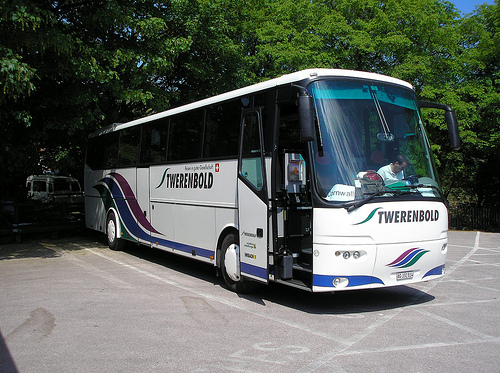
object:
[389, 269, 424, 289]
license plate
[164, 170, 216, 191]
writing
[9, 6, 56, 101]
leaves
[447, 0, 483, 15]
sky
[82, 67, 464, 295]
bus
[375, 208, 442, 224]
word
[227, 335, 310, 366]
es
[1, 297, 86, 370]
ground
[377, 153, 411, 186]
man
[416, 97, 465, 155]
mirror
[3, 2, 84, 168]
trees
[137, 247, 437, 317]
shadow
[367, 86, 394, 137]
wipers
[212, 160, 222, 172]
square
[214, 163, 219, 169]
cross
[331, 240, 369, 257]
headlights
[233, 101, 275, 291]
door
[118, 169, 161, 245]
stripes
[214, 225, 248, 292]
caps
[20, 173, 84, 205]
van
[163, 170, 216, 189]
twerenbold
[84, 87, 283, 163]
windows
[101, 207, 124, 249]
back wheel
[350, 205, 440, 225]
logo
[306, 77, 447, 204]
windshield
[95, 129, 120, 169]
side window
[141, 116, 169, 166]
side window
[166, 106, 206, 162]
side window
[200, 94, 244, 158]
side window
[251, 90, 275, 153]
side window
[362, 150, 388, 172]
driver's seat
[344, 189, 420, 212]
windshield wiper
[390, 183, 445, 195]
windshield wiper